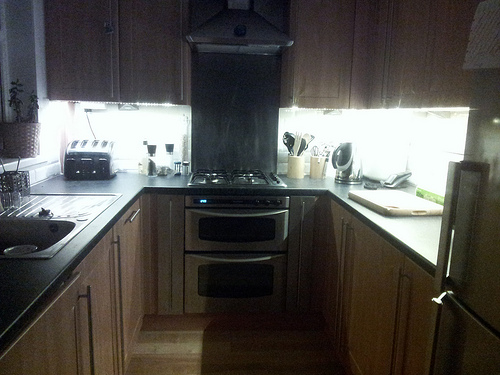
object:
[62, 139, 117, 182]
toaster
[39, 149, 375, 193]
counter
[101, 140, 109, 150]
slots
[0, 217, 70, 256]
sink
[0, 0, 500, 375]
kitchen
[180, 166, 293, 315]
oven range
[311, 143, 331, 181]
utensils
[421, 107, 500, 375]
refrigerator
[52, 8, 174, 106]
cupboards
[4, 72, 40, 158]
plant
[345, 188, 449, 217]
cutting board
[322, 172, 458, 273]
counter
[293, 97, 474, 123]
light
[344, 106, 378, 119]
bright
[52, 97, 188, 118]
light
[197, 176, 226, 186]
burners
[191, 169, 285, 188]
stove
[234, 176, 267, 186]
burner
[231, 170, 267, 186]
right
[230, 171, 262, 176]
back burner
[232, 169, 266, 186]
right burner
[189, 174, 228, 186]
front left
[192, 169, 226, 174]
back left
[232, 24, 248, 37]
blue light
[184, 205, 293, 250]
top oven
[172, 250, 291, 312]
bottom oven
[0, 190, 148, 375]
cabinet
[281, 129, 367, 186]
cooking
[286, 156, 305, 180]
vase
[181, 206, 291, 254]
oven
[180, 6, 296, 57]
range hood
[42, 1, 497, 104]
cabinets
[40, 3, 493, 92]
upper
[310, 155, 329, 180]
holder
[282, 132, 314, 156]
spoons and spatulas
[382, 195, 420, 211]
wood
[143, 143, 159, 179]
grinders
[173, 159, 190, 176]
salt & pepper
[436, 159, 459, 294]
handle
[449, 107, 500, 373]
freezer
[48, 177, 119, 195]
small part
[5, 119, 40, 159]
basket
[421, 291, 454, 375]
handle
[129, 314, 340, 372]
floor